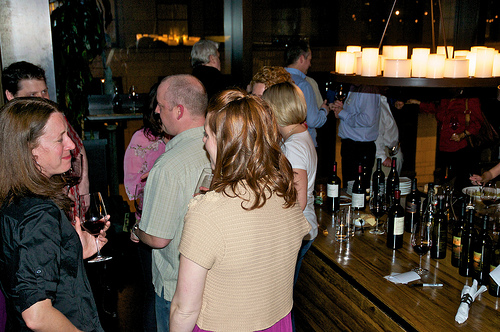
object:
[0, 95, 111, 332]
lady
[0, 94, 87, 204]
brown hair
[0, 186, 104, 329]
shirt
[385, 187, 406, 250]
wine bottle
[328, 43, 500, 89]
lights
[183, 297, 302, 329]
dress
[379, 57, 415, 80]
candles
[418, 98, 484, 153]
shirt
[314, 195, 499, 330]
bar top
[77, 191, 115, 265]
glass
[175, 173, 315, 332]
sweater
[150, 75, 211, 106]
bald spot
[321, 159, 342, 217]
beverage bottles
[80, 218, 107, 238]
red wine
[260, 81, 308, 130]
hair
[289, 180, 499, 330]
table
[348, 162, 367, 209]
bottles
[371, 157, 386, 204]
bottles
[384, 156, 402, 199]
bottles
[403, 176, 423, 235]
bottles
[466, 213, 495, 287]
bottles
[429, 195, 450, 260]
bottles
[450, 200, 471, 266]
bottles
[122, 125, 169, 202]
pink shirt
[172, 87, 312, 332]
woman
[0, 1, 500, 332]
bar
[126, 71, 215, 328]
man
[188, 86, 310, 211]
hair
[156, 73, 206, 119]
hair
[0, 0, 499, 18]
ceiling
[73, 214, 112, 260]
hand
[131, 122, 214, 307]
shirt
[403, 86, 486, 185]
person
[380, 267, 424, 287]
napkin